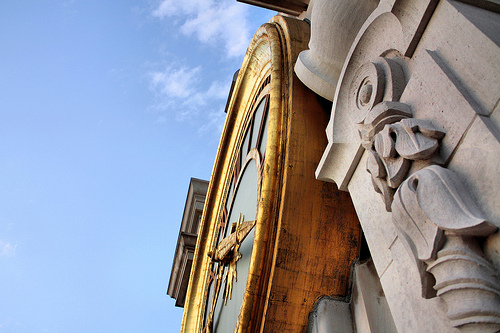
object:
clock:
[185, 16, 361, 333]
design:
[389, 163, 497, 331]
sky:
[0, 0, 278, 331]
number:
[248, 103, 270, 163]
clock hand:
[211, 219, 253, 262]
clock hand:
[203, 264, 220, 331]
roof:
[165, 178, 209, 308]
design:
[340, 60, 386, 127]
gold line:
[242, 111, 257, 149]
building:
[164, 0, 362, 333]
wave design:
[366, 117, 446, 209]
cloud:
[154, 1, 251, 56]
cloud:
[146, 60, 241, 133]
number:
[225, 154, 243, 191]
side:
[272, 173, 358, 302]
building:
[292, 0, 496, 330]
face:
[180, 27, 271, 333]